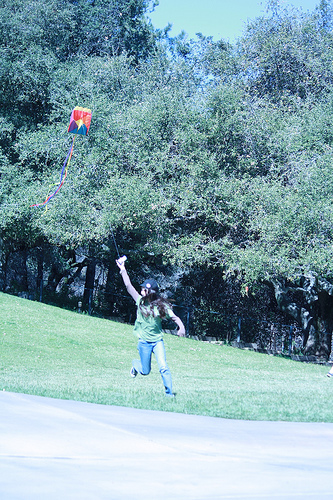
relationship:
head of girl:
[123, 274, 170, 304] [122, 273, 182, 394]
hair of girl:
[141, 293, 166, 308] [122, 273, 182, 394]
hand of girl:
[110, 245, 133, 272] [122, 273, 182, 394]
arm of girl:
[95, 256, 150, 302] [122, 273, 182, 394]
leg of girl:
[149, 348, 179, 390] [122, 273, 182, 394]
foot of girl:
[124, 364, 180, 398] [122, 273, 182, 394]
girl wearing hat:
[122, 273, 182, 394] [145, 272, 167, 297]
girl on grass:
[122, 273, 182, 394] [12, 319, 80, 364]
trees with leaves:
[160, 133, 310, 254] [201, 99, 277, 181]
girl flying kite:
[122, 273, 182, 394] [59, 82, 97, 166]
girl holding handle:
[122, 273, 182, 394] [106, 240, 139, 271]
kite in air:
[59, 82, 97, 166] [180, 6, 216, 35]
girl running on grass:
[122, 273, 182, 394] [12, 319, 80, 364]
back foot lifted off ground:
[125, 361, 138, 375] [190, 364, 238, 396]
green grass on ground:
[12, 319, 80, 364] [190, 364, 238, 396]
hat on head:
[145, 272, 167, 297] [123, 274, 170, 304]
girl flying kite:
[122, 273, 182, 354] [59, 82, 97, 166]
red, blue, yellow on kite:
[66, 101, 94, 142] [59, 82, 97, 166]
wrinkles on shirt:
[123, 290, 174, 340] [133, 306, 169, 343]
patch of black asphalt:
[37, 413, 95, 461] [88, 427, 163, 473]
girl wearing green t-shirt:
[122, 273, 182, 394] [133, 306, 169, 343]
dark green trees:
[25, 8, 109, 55] [160, 133, 310, 254]